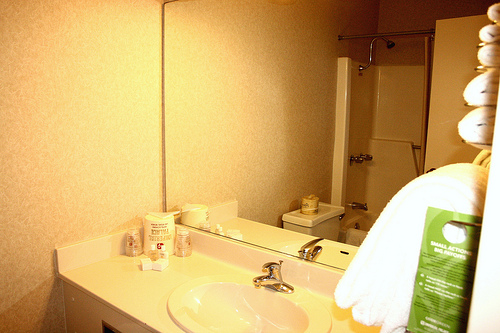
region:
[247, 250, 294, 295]
metal faucet on sink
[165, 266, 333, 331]
white porcelain sink basin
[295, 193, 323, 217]
roll of toilet tissue on top of toilet tank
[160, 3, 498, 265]
large wall mirror in bathroom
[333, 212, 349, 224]
toilet silver handle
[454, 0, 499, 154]
white stack of white towels in bathroom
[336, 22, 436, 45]
metal shower curtain pole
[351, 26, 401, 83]
metal shower head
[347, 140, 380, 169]
metal shower handles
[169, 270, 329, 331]
the sink is white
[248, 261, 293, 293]
the fixture is silver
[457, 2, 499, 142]
the towels are stacked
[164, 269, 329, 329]
the counter is white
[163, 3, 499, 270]
a reflection in the mirror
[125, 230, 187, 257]
cups upside down on counter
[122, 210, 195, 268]
toiletries on the counter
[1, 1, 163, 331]
the walls are beige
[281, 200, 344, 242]
the toilet is white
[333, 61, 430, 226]
the shower is white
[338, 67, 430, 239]
Shower in a bath room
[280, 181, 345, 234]
Comode top in a bathroom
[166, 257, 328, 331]
Sink in the bathroom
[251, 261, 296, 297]
Chrome fixtures on the sink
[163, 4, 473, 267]
Mirror in the bathroom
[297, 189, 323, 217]
Extra roll of tissue paper on the back of the comode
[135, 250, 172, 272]
Small soaps on the vanity.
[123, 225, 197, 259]
Candles on the vanity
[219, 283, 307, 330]
The sink has pink in the color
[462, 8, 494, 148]
Towels to the right of the vanity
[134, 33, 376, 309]
a large mirror over a bathroom sink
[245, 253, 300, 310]
a silver faucet for a bathroom sink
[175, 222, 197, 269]
plastic cups on a bathroom vanity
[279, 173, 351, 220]
the reflection of a roll of toilet paper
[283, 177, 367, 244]
the reflection of a toilet bowl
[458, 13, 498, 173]
a stack of white towels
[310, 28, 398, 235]
the reflection of a bathroom shower and tub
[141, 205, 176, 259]
a plastic ice bucket on a bathroom vanity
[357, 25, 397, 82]
a long shower head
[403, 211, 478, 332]
a green door tag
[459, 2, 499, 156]
white towels folded and stacked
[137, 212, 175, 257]
extra roll of toilet paper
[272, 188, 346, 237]
extra roll of toilet paper on toilet tank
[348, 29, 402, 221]
shower head, faucet, and water controls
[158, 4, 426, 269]
large mirror in the bathroom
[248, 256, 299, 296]
faucet with single water control on sink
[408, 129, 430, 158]
end of a towel bar in shower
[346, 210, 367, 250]
front area of the tub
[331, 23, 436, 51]
shower curtain rod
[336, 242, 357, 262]
water overflow in sink